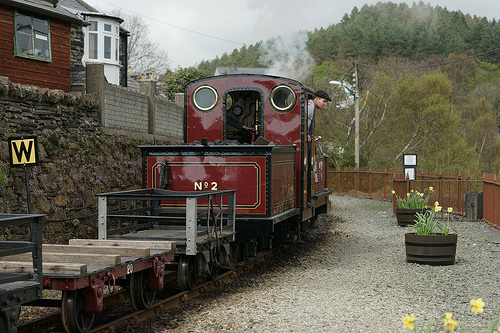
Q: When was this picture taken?
A: Daytime.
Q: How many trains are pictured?
A: One.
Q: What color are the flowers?
A: Yellow.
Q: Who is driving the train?
A: The conductor.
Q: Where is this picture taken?
A: At a train station.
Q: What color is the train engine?
A: Red.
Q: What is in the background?
A: Trees and a hill.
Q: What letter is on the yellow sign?
A: W.